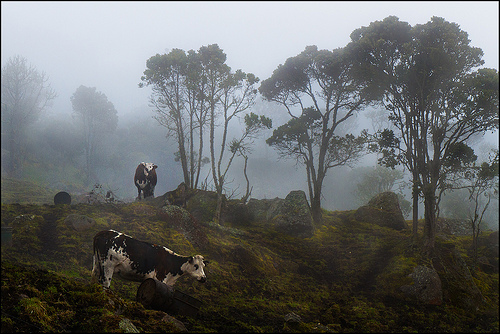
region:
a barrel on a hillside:
[133, 275, 205, 325]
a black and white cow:
[90, 225, 218, 319]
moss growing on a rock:
[377, 248, 427, 289]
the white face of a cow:
[188, 254, 206, 280]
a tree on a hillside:
[262, 53, 362, 245]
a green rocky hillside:
[4, 175, 494, 332]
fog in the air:
[0, 4, 494, 203]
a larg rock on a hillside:
[260, 185, 313, 232]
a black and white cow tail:
[89, 231, 101, 277]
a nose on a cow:
[194, 270, 208, 284]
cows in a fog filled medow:
[0, 32, 282, 332]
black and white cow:
[66, 215, 265, 332]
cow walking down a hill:
[48, 209, 250, 331]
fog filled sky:
[1, 20, 364, 155]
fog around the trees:
[145, 32, 498, 230]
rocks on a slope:
[233, 179, 494, 331]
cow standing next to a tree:
[124, 34, 271, 214]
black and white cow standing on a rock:
[116, 122, 237, 232]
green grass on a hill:
[248, 232, 400, 325]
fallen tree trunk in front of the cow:
[74, 215, 269, 332]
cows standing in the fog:
[26, 88, 385, 326]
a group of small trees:
[123, 15, 478, 238]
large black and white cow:
[68, 202, 226, 303]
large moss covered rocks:
[237, 154, 464, 332]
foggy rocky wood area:
[36, 44, 468, 259]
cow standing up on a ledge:
[123, 149, 197, 233]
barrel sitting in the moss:
[44, 181, 74, 218]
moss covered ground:
[60, 195, 456, 319]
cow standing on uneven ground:
[76, 220, 233, 309]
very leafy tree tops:
[318, 7, 489, 125]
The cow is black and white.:
[76, 219, 230, 320]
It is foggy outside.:
[22, 56, 499, 244]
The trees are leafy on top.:
[115, 36, 492, 171]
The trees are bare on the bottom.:
[123, 75, 497, 253]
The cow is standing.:
[103, 153, 168, 211]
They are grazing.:
[17, 165, 414, 315]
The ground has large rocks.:
[153, 191, 345, 318]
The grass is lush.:
[96, 192, 214, 287]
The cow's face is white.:
[175, 251, 225, 282]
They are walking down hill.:
[73, 183, 444, 330]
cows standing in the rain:
[97, 128, 214, 302]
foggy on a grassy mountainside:
[54, 108, 424, 286]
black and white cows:
[96, 143, 222, 309]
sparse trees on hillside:
[115, 31, 475, 238]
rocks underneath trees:
[174, 174, 335, 243]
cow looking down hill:
[79, 229, 276, 316]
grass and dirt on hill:
[147, 221, 426, 321]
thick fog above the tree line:
[30, 25, 432, 120]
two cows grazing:
[82, 143, 214, 312]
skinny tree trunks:
[175, 95, 239, 225]